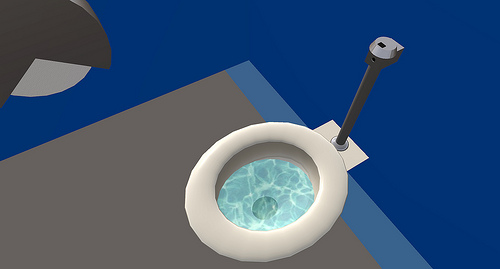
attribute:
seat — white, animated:
[185, 122, 347, 263]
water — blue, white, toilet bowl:
[217, 157, 315, 231]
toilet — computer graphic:
[184, 118, 370, 262]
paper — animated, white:
[10, 59, 92, 99]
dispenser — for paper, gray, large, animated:
[0, 0, 112, 109]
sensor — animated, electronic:
[369, 56, 378, 63]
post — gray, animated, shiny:
[338, 36, 405, 146]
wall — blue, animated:
[251, 1, 500, 268]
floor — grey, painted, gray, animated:
[0, 70, 385, 268]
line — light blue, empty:
[225, 60, 432, 268]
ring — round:
[328, 136, 350, 153]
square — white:
[315, 119, 369, 171]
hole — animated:
[252, 196, 278, 220]